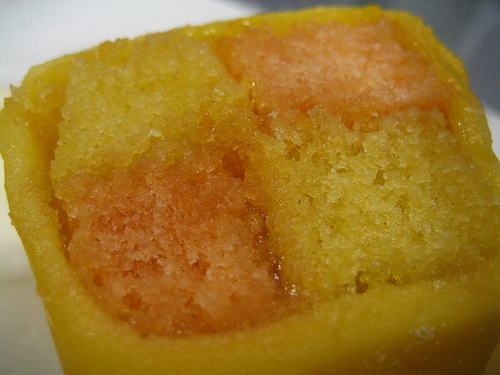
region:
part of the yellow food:
[26, 88, 88, 143]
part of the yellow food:
[124, 55, 192, 104]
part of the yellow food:
[277, 140, 332, 196]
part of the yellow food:
[405, 203, 449, 253]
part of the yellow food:
[398, 127, 435, 164]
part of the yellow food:
[309, 218, 346, 275]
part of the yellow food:
[413, 301, 465, 358]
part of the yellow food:
[305, 313, 360, 363]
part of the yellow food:
[67, 313, 107, 359]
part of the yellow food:
[63, 128, 98, 158]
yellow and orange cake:
[7, 3, 499, 373]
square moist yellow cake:
[5, 3, 499, 365]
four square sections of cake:
[60, 15, 496, 339]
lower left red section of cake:
[46, 135, 296, 334]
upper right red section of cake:
[205, 15, 454, 125]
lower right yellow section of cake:
[247, 99, 498, 289]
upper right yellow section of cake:
[40, 35, 257, 185]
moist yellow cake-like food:
[10, 6, 499, 371]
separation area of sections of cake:
[210, 138, 315, 320]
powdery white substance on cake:
[370, 315, 445, 373]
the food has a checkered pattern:
[1, 0, 498, 370]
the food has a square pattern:
[1, 0, 499, 371]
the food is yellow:
[2, 0, 495, 372]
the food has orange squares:
[78, 14, 431, 346]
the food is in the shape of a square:
[1, 3, 498, 373]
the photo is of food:
[1, 0, 496, 373]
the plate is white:
[5, 0, 499, 372]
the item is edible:
[4, 3, 497, 373]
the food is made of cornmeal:
[3, 2, 499, 371]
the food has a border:
[1, 0, 498, 372]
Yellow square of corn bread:
[6, 6, 493, 371]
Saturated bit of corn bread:
[65, 154, 292, 330]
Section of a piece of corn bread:
[63, 59, 240, 177]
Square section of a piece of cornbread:
[266, 107, 493, 287]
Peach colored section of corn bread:
[220, 27, 437, 111]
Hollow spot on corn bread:
[21, 93, 69, 165]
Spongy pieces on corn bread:
[324, 156, 396, 213]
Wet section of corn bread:
[257, 229, 310, 314]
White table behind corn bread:
[2, 2, 244, 81]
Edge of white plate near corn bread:
[475, 104, 498, 161]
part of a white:
[321, 253, 328, 261]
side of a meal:
[267, 195, 288, 220]